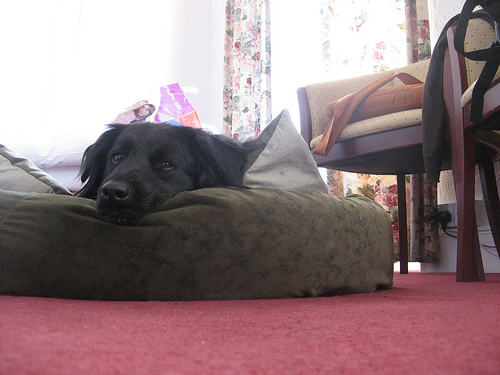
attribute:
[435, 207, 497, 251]
power cord — black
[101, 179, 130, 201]
nose — wet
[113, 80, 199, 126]
bag — for shopping, plastic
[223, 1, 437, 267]
drapes — flowered, patterned, floral, decorated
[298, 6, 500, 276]
chair — on the side, wooden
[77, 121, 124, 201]
ear — long, hairy, furry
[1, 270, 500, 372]
floor — carpet, carpeted, red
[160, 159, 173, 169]
eye — black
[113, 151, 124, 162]
eye — black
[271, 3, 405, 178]
window — lit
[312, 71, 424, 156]
bag — light brown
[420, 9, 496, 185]
jacket — black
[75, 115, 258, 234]
dog — black, sad, brown, lying down, lying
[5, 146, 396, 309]
bed — green, pillow